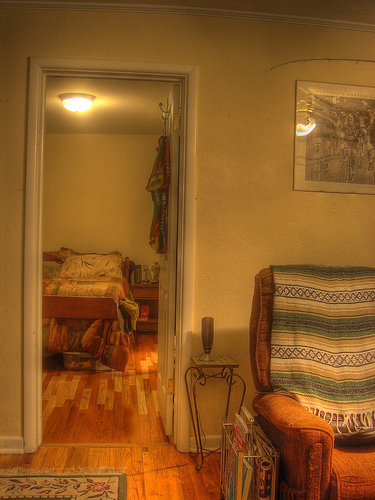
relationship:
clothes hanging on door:
[146, 128, 172, 257] [148, 83, 175, 444]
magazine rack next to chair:
[209, 406, 281, 500] [247, 253, 374, 497]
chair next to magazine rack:
[247, 253, 374, 497] [209, 406, 281, 500]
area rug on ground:
[1, 464, 129, 499] [5, 451, 216, 500]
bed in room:
[44, 247, 137, 368] [40, 83, 180, 439]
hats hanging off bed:
[114, 297, 141, 337] [44, 247, 137, 368]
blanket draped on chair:
[270, 256, 375, 428] [247, 253, 374, 497]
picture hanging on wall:
[289, 74, 374, 209] [3, 9, 372, 427]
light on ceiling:
[55, 91, 100, 119] [42, 76, 169, 140]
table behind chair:
[184, 349, 246, 471] [247, 253, 374, 497]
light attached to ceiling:
[55, 91, 100, 119] [42, 76, 169, 140]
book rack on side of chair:
[209, 406, 281, 500] [247, 253, 374, 497]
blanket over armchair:
[270, 256, 375, 428] [247, 253, 374, 497]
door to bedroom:
[148, 83, 175, 444] [40, 83, 180, 439]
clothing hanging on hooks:
[146, 128, 172, 257] [157, 96, 173, 123]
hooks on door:
[157, 96, 173, 123] [148, 83, 175, 444]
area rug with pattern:
[1, 464, 129, 499] [84, 483, 111, 499]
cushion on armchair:
[329, 440, 374, 497] [247, 253, 374, 497]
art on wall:
[289, 74, 374, 209] [3, 9, 372, 427]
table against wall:
[184, 349, 246, 471] [3, 9, 372, 427]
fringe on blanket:
[306, 404, 372, 438] [270, 256, 375, 428]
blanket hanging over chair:
[270, 256, 375, 428] [247, 253, 374, 497]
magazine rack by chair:
[209, 406, 281, 500] [247, 253, 374, 497]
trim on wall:
[185, 436, 234, 452] [3, 9, 372, 427]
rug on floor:
[1, 464, 129, 499] [0, 328, 229, 499]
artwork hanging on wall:
[289, 74, 374, 209] [3, 9, 372, 427]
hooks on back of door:
[157, 101, 169, 114] [148, 83, 175, 444]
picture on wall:
[289, 74, 374, 209] [3, 9, 372, 427]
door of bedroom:
[148, 83, 175, 444] [40, 83, 180, 439]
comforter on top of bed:
[45, 273, 124, 298] [44, 247, 137, 368]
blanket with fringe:
[270, 256, 375, 428] [306, 404, 372, 438]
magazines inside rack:
[231, 422, 252, 493] [209, 406, 281, 500]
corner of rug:
[109, 469, 133, 487] [1, 464, 129, 499]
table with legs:
[184, 349, 246, 471] [184, 366, 213, 480]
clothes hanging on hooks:
[146, 128, 172, 257] [157, 96, 173, 123]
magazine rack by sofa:
[209, 406, 281, 500] [247, 253, 374, 497]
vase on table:
[198, 315, 217, 362] [184, 349, 246, 471]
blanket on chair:
[270, 256, 375, 428] [247, 253, 374, 497]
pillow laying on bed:
[60, 252, 122, 280] [44, 247, 137, 368]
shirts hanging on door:
[146, 128, 172, 257] [148, 83, 175, 444]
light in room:
[55, 91, 100, 119] [40, 83, 180, 439]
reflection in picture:
[299, 115, 316, 140] [289, 74, 374, 209]